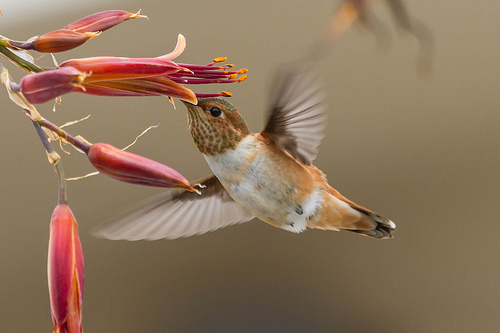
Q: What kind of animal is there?
A: Hummingbird.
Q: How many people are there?
A: None.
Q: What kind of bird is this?
A: Hummingbird.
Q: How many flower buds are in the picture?
A: 6.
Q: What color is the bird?
A: Brown and white.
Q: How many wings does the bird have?
A: White.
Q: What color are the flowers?
A: Red and orange.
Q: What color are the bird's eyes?
A: Brown.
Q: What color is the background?
A: Brown.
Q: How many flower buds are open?
A: 1.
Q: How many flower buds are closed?
A: 5.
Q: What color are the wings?
A: White.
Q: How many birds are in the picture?
A: One.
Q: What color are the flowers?
A: Pink.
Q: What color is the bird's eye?
A: Black.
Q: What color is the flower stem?
A: Gray and green.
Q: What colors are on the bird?
A: Brown and white.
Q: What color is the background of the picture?
A: Brown.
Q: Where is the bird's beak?
A: In the flower.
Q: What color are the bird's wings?
A: Brown and white.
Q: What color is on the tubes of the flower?
A: Orange.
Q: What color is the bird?
A: Brown.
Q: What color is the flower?
A: Red.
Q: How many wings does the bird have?
A: Two.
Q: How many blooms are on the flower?
A: Six.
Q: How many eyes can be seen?
A: One.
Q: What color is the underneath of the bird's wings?
A: White.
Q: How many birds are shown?
A: One.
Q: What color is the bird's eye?
A: Black.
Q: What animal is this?
A: Hummingbird.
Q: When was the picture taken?
A: During the day.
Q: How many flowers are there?
A: Five.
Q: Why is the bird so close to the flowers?
A: To get nectar.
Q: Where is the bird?
A: In the air.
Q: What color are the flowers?
A: Pink and red.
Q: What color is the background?
A: Brown.